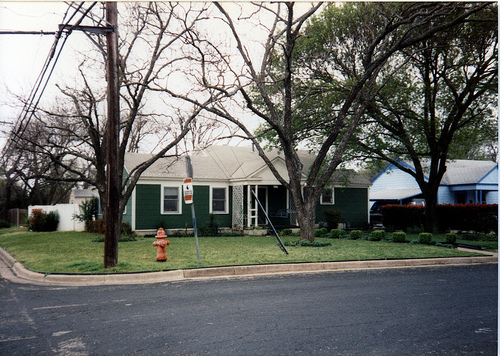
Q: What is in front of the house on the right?
A: The tree is in front of the house.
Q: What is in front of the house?
A: The tree is in front of the house.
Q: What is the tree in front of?
A: The tree is in front of the house.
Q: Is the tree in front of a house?
A: Yes, the tree is in front of a house.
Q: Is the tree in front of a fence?
A: No, the tree is in front of a house.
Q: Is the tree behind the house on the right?
A: No, the tree is in front of the house.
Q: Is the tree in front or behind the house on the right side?
A: The tree is in front of the house.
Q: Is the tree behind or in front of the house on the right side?
A: The tree is in front of the house.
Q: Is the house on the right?
A: Yes, the house is on the right of the image.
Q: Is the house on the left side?
A: No, the house is on the right of the image.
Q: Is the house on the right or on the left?
A: The house is on the right of the image.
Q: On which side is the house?
A: The house is on the right of the image.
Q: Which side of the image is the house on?
A: The house is on the right of the image.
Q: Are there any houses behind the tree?
A: Yes, there is a house behind the tree.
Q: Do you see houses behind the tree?
A: Yes, there is a house behind the tree.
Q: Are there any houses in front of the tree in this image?
A: No, the house is behind the tree.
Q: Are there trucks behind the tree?
A: No, there is a house behind the tree.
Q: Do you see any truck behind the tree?
A: No, there is a house behind the tree.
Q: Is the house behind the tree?
A: Yes, the house is behind the tree.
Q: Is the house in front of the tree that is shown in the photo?
A: No, the house is behind the tree.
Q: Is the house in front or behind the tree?
A: The house is behind the tree.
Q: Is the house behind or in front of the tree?
A: The house is behind the tree.